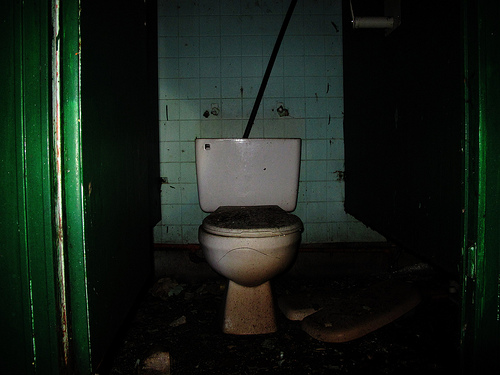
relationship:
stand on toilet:
[224, 280, 275, 337] [197, 133, 303, 336]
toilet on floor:
[197, 133, 303, 336] [107, 265, 496, 372]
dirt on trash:
[145, 276, 448, 368] [107, 265, 496, 372]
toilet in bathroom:
[197, 133, 303, 336] [0, 0, 497, 372]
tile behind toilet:
[267, 97, 289, 120] [197, 133, 303, 336]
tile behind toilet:
[241, 95, 264, 118] [197, 133, 303, 336]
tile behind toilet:
[242, 118, 265, 136] [197, 133, 303, 336]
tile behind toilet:
[219, 97, 244, 120] [197, 133, 303, 336]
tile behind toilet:
[198, 95, 224, 122] [197, 133, 303, 336]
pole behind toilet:
[243, 2, 298, 142] [197, 133, 303, 336]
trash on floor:
[147, 274, 425, 370] [107, 265, 496, 372]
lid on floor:
[302, 272, 420, 345] [107, 265, 496, 372]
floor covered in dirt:
[107, 265, 496, 372] [145, 276, 448, 368]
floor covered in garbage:
[107, 265, 496, 372] [118, 267, 444, 374]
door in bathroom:
[337, 0, 471, 282] [0, 0, 497, 372]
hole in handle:
[360, 0, 390, 15] [341, 0, 402, 37]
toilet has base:
[197, 133, 303, 336] [224, 280, 275, 337]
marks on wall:
[328, 166, 346, 182] [151, 2, 386, 244]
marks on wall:
[196, 103, 222, 124] [151, 2, 386, 244]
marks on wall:
[273, 101, 294, 124] [151, 2, 386, 244]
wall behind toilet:
[151, 2, 386, 244] [197, 133, 303, 336]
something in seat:
[219, 209, 287, 223] [203, 208, 306, 234]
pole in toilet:
[243, 2, 298, 142] [197, 133, 303, 336]